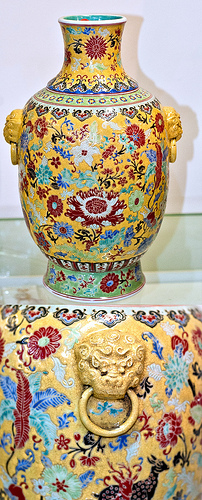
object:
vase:
[3, 15, 182, 304]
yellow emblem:
[164, 105, 183, 165]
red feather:
[10, 367, 32, 445]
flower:
[28, 326, 62, 359]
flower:
[34, 462, 85, 500]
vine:
[54, 432, 105, 471]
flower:
[70, 140, 102, 168]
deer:
[92, 455, 170, 500]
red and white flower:
[66, 187, 126, 230]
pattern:
[30, 87, 155, 106]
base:
[44, 263, 146, 302]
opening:
[59, 14, 124, 24]